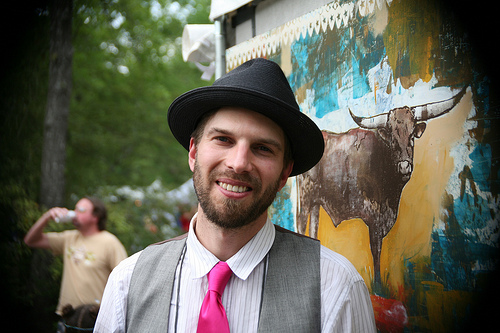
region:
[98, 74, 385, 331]
this is a man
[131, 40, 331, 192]
this is a black hat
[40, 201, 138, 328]
the man is drinking from a bpttle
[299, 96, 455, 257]
a painting of a cow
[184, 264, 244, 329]
a pink tie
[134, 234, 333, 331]
a gray half coat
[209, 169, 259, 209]
his teeth are white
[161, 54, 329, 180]
black hat on a man's head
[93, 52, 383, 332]
a smiling man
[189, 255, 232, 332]
pink tie on a man's shirt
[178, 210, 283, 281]
collar of a man's shirt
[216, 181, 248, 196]
a man's white teeth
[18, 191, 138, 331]
man in the background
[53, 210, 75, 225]
drink in a man's hand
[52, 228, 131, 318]
tan tee shirt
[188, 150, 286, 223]
brown facial hair on a man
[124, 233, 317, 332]
grey vest on a man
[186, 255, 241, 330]
Pink tie on a man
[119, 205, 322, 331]
Vest on a man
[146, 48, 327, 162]
Black hat on a man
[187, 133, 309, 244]
Beard on a man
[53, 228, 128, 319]
Beige t shirt on a man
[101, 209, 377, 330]
Stripped shirt on a man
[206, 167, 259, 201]
Smile on a man's face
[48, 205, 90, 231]
Can held up to a man's face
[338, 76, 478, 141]
Horns on a bull painting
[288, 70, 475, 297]
Bull painting on a wall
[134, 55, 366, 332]
This is a person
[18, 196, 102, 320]
Section of the background of a person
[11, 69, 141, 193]
Section of the background of a person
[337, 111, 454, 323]
Section of the background of a person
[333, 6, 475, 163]
Section of the background of a person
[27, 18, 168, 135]
Section of the background of a person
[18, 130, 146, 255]
Section of the background of a person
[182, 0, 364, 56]
Section of the background of a person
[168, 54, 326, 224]
The man is wearing a hat.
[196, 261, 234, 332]
The man is wearing a tie.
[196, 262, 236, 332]
The tie is pink in color.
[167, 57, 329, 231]
The hat is black in color.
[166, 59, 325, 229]
The man is smiling.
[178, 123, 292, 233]
The man has a brown beard.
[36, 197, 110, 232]
The man is drinking from a can.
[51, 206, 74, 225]
The can is silver in color.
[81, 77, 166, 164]
The tree leaves in the background are green.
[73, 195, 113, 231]
The man's hair is brown in color.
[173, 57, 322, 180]
The black hat the man is wearing.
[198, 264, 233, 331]
The pink tie the man is wearing.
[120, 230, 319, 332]
The gray vest the man is wearing.